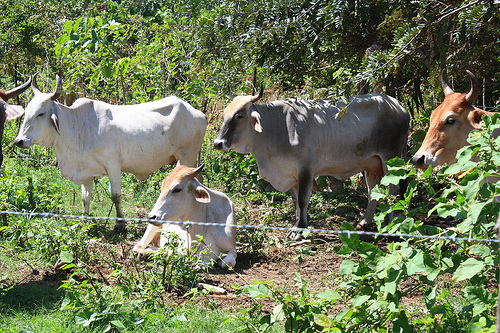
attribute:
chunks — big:
[52, 74, 69, 101]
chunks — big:
[29, 72, 44, 91]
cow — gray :
[222, 90, 439, 190]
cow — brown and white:
[133, 162, 239, 267]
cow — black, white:
[218, 81, 416, 172]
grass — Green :
[28, 275, 270, 332]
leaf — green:
[365, 160, 497, 331]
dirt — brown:
[234, 219, 396, 312]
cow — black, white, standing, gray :
[211, 83, 412, 238]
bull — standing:
[13, 67, 209, 229]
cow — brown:
[409, 76, 499, 169]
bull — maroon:
[399, 65, 497, 192]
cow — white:
[0, 87, 209, 250]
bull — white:
[6, 87, 216, 250]